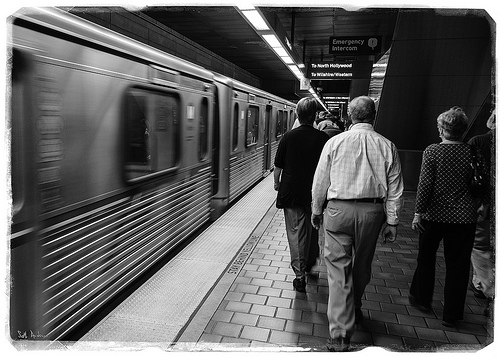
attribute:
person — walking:
[271, 94, 333, 297]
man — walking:
[309, 96, 399, 352]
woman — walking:
[409, 107, 479, 329]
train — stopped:
[10, 8, 296, 341]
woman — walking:
[467, 108, 496, 299]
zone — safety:
[76, 167, 277, 345]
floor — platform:
[75, 168, 490, 347]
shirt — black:
[274, 125, 328, 207]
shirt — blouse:
[412, 140, 479, 221]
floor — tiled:
[198, 208, 490, 348]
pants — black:
[408, 220, 476, 322]